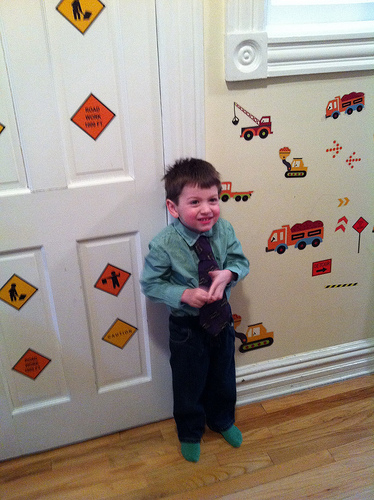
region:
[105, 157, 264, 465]
Kid dressed professionally.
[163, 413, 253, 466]
Kid has blue socks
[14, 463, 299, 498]
Wooden floor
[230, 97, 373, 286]
Construction work in the wallpaper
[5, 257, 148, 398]
Construction stickers on the door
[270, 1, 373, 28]
There are no blinds on the window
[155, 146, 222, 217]
Kids hair is short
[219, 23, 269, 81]
Circular design on corner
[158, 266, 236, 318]
Kid is playing with hands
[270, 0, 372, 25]
Its sunny outside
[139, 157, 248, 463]
child is standing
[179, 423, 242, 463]
child wearing green socks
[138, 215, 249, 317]
child wearing green shirt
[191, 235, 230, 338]
child wearing large tie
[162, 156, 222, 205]
child has brown hair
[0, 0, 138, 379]
orange and yellow stickers on door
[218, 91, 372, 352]
stickers on wall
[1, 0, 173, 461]
white door behind child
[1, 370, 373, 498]
wooden floor under child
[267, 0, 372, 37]
window is above child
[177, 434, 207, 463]
The left green sock the boy is wearing.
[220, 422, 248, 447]
The right green sock the boy is wearing.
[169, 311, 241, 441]
The dark pants the boy is wearing.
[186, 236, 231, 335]
The tie the boy is wearing.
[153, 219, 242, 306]
The green dress shirt the boy is wearing.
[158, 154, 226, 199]
The hair of the boy standing up.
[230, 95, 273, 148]
The sticker on the wall of the truck with a crane and ball.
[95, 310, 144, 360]
The caution sticker on the door.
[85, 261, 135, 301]
The orange sticker with a person figure holding a flag on the door.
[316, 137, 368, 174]
The two dotted arrows on the wall.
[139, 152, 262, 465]
A little boy is wearing a tie.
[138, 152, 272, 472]
A little boy is wearing a shirt with matching green socks.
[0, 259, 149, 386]
Construction sign stickers on back of door.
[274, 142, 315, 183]
A bulldozer sticker is on the wall with other stickers.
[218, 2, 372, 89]
Nice white moulding around window in room.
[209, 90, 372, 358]
Large group of construction stickers on a wall.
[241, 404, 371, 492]
Hardwood flooring on the floor of a room.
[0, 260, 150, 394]
Orange and yellow construction sign stickers on door.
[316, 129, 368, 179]
Red arrow stickers on the wall of a room.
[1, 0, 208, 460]
Large white interior door with construction stickers.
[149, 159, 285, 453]
a little boy who looks shy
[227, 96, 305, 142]
a little tractor on the wall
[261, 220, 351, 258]
a truck sticker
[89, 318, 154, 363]
a yellow caution sticker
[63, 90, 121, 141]
a red road work sticker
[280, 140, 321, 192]
a yellow trailer sticker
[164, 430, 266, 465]
green socks of the boy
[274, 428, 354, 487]
a wooden floor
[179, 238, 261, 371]
the tie the kid is wearing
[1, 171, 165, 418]
a white door with stickers on it